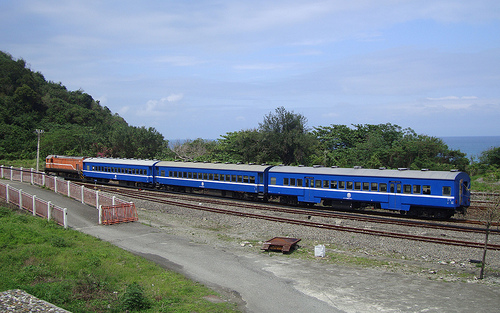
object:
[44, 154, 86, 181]
car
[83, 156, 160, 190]
car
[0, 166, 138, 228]
fence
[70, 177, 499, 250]
tracks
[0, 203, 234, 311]
grass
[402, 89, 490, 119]
clouds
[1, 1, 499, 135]
sky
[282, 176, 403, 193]
windows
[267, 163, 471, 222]
car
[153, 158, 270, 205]
car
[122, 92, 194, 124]
clouds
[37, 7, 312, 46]
clouds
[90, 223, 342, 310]
pathway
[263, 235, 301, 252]
metal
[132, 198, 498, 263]
gravel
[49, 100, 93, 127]
bushes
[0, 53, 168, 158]
hill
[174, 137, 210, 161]
bush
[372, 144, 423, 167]
brush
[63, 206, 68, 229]
post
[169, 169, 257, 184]
windows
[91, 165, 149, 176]
windows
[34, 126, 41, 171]
pole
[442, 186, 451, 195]
window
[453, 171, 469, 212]
front